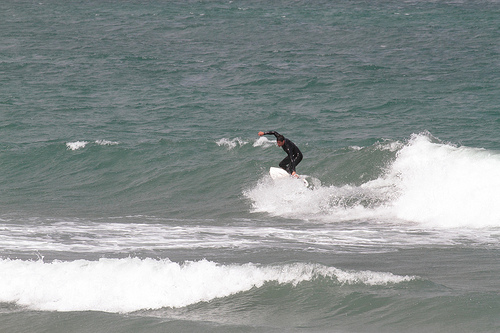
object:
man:
[257, 130, 304, 178]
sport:
[199, 112, 324, 201]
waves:
[0, 122, 500, 326]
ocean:
[2, 0, 499, 332]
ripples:
[0, 3, 500, 330]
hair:
[276, 136, 285, 143]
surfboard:
[268, 167, 292, 184]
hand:
[256, 131, 265, 135]